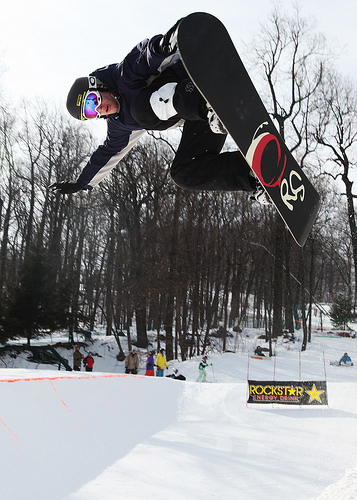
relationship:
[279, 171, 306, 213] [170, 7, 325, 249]
rs logo on snowboard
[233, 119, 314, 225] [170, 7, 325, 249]
rs logo on snowboard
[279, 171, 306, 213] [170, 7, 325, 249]
rs logo painted on snowboard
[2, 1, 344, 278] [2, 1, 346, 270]
cloud cover hanging in sky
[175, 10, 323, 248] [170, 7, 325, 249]
bottom belonging to snowboard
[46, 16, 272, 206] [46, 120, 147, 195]
man extending arm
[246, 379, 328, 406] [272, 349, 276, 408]
banner attached to pole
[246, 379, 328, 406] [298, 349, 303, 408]
banner attached to pole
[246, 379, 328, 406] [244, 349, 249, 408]
banner attached to pole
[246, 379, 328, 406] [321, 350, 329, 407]
banner attached to pole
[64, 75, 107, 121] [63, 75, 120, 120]
helmet worn on head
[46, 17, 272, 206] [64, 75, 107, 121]
man wearing helmet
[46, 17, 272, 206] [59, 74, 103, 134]
man wearing goggles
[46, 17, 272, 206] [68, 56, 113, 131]
man wearing goggles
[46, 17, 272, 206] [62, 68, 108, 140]
man wearing goggles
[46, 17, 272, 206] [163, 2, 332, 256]
man on a snowboard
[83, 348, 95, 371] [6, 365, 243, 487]
skier on slope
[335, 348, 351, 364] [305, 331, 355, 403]
skier on slope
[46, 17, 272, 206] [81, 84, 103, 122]
man wears goggles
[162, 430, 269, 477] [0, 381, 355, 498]
shadow on snow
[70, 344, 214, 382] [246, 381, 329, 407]
fans watching event